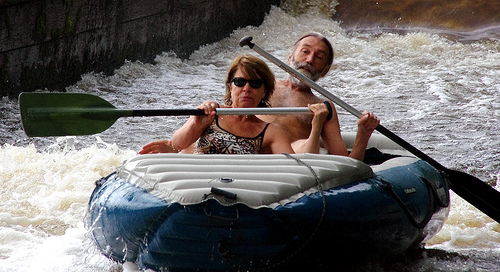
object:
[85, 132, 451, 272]
raft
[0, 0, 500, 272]
water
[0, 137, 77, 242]
splash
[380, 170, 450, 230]
handles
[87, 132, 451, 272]
boat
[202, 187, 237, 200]
handle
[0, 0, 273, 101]
block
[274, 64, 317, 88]
writing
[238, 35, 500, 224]
boat stick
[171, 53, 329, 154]
girl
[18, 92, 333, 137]
oar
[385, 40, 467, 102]
wave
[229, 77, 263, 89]
sunglasses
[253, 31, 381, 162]
man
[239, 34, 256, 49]
knob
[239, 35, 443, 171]
stick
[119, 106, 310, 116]
stick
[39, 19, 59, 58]
moss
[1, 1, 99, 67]
concrete wall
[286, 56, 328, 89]
beard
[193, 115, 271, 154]
shirt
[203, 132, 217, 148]
design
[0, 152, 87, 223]
froth